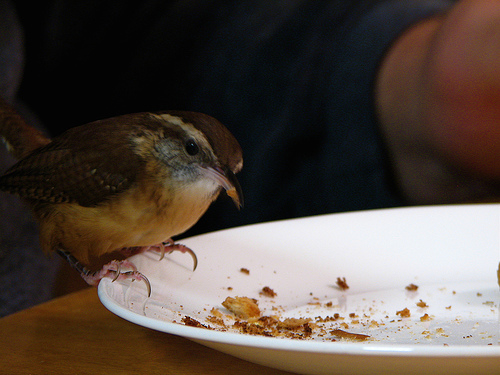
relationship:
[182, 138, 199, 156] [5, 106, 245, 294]
eye of bird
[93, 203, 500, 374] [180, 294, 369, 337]
plate with food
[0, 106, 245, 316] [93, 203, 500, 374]
bird on plate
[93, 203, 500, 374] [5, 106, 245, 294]
plate with bird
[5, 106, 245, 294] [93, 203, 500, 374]
bird on plate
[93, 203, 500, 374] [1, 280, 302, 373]
plate on table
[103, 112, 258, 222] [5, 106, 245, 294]
beak on bird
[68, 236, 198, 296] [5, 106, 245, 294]
feet on bird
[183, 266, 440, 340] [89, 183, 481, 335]
crumbs on plate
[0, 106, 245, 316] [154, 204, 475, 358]
bird on plate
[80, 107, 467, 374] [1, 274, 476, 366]
plate on table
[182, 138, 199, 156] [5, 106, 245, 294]
eye on bird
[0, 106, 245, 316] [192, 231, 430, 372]
bird on plate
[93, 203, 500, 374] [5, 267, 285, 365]
plate on table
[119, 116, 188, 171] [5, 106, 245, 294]
feathers on bird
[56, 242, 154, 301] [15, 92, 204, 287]
leg of bird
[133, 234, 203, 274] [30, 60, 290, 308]
leg of bird